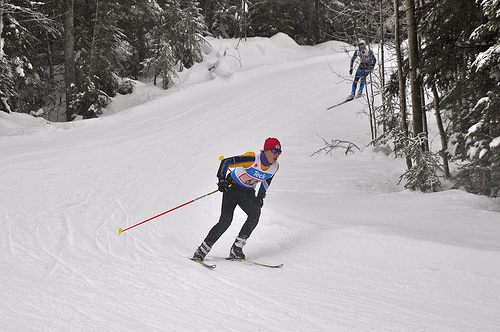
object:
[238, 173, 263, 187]
number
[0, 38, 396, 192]
slope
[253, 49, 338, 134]
trail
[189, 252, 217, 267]
ski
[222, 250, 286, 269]
ski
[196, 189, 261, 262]
man pants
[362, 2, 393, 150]
trees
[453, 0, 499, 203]
trees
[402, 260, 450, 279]
track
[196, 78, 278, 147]
track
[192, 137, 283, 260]
man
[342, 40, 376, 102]
man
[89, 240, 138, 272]
track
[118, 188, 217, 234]
pole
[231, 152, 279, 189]
racing vest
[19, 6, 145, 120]
tree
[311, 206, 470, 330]
ski trail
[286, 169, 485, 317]
snow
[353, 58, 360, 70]
ski pole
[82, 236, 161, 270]
marks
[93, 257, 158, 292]
track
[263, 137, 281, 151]
cap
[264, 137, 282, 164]
head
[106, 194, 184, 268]
track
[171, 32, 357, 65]
snow banks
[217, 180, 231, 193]
hand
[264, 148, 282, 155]
goggles